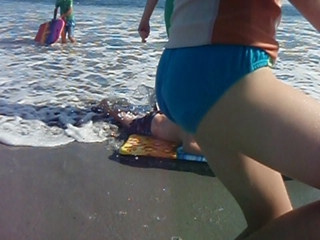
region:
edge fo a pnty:
[207, 99, 212, 105]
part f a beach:
[110, 179, 131, 214]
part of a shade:
[220, 74, 256, 151]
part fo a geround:
[130, 170, 150, 204]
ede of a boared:
[164, 141, 190, 181]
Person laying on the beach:
[96, 79, 250, 169]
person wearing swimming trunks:
[142, 32, 263, 125]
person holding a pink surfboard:
[36, 19, 70, 41]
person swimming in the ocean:
[92, 82, 217, 151]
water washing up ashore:
[4, 94, 89, 166]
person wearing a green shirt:
[52, 2, 78, 15]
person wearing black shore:
[131, 97, 156, 137]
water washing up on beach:
[4, 101, 96, 153]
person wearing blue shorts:
[59, 12, 80, 42]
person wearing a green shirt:
[54, 2, 77, 23]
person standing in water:
[29, 0, 78, 47]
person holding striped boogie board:
[30, 0, 76, 49]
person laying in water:
[94, 96, 214, 157]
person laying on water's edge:
[96, 97, 210, 168]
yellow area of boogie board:
[115, 130, 181, 163]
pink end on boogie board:
[50, 17, 63, 45]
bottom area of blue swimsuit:
[152, 38, 275, 137]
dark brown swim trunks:
[128, 108, 162, 140]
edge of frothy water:
[0, 124, 120, 148]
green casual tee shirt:
[53, 0, 74, 21]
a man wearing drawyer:
[119, 15, 312, 139]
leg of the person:
[211, 168, 305, 218]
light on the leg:
[251, 165, 288, 203]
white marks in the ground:
[110, 200, 207, 233]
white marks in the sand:
[109, 190, 171, 234]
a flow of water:
[20, 113, 99, 146]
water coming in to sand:
[10, 100, 107, 141]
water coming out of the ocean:
[19, 92, 139, 162]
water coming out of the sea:
[26, 94, 106, 152]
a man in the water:
[32, 12, 102, 48]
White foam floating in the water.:
[14, 60, 138, 88]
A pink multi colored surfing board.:
[30, 16, 66, 45]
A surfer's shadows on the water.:
[3, 83, 106, 128]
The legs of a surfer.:
[208, 96, 318, 216]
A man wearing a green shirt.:
[51, 1, 76, 47]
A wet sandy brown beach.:
[30, 167, 182, 236]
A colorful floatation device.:
[119, 133, 211, 181]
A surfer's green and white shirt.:
[125, 1, 301, 55]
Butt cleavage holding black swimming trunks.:
[128, 107, 168, 140]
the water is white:
[14, 113, 45, 139]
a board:
[40, 19, 67, 40]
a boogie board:
[36, 18, 69, 44]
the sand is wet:
[59, 167, 124, 211]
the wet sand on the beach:
[102, 190, 144, 219]